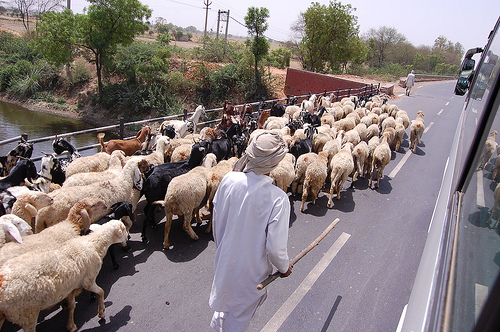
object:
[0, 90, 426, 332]
sheep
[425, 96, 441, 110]
road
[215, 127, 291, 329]
man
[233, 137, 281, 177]
turban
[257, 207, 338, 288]
stick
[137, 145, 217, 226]
goat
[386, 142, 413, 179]
line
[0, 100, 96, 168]
water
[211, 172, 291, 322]
dress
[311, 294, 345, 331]
shadow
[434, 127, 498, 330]
windows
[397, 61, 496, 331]
bus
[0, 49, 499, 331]
bridge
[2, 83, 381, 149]
guard rail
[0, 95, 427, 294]
goats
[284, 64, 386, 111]
wall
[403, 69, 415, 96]
man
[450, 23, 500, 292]
mirror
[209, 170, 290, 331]
clothing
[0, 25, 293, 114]
bushes